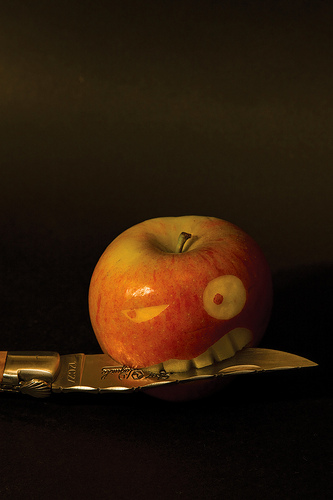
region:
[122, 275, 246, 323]
eyes carved onto the apple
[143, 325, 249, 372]
teeth carved on to the apple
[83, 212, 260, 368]
an apple carved into a face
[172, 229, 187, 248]
the apple stem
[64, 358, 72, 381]
a number on the blade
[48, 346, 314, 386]
the blade of a knife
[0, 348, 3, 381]
the handle is wood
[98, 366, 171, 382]
engraving on the knife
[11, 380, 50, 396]
desing on the knife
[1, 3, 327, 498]
the background is solid black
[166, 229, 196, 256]
Stem of apple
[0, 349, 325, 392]
Old pocket knife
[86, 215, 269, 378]
The apple is red and yellow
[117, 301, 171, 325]
Squinty eye of apple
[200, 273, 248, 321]
Open eye of apple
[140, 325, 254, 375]
The apple's teeth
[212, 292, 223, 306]
The apple's pupil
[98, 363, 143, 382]
Carvings in the knife's blade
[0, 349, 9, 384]
Handle of pocket knife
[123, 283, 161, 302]
Light reflection on apple from camera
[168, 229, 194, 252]
stem of the apple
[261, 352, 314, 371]
a knife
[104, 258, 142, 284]
the apple is red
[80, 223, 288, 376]
a apple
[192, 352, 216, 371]
teeth on the apple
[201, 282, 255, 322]
an eye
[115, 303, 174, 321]
right eye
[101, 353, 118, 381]
writing on the knife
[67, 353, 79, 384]
writing on the knife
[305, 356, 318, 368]
the point of the knife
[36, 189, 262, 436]
an apple on the table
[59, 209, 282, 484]
a red apple on the table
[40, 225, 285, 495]
an apple with a face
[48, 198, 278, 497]
a red apple with a face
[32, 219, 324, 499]
a knife in an apple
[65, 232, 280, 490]
knife with a red apple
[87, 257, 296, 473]
a silver knife in the apple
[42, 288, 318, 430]
a pocket knife in the apple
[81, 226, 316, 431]
a pocket knife in the red apple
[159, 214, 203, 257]
stem of the fruit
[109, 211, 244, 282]
top of the fruit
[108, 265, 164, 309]
eyebrow of the fruit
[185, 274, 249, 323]
eye on the fruit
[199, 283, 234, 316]
round eye on fruit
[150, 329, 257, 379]
teeth of the fruit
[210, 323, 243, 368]
one tooth on the fruit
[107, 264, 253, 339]
two eyes on the fruit